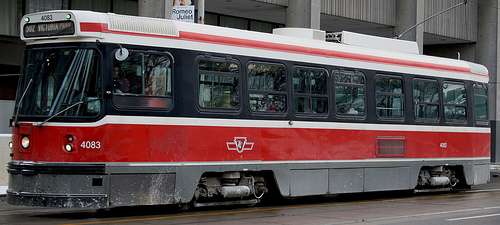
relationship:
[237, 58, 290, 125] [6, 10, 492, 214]
window on bus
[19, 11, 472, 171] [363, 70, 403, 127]
bus has window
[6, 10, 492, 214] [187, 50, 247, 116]
bus has window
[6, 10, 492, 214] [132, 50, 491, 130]
bus has window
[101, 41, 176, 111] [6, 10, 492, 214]
window on bus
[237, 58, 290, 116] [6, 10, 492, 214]
window on bus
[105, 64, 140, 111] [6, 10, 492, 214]
conductor in bus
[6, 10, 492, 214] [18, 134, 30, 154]
bus has headlight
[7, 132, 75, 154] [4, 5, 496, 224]
headlight on train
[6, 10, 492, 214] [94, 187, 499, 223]
bus on street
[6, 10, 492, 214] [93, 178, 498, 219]
bus on road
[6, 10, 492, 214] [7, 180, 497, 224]
bus on road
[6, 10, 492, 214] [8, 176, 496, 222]
bus on road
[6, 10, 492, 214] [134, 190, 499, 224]
bus on street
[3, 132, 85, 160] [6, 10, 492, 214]
headlights on bus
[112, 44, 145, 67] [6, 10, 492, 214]
mirror on bus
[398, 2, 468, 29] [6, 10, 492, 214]
pole connect to bus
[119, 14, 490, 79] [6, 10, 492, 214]
roof on bus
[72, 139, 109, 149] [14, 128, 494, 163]
tram number on background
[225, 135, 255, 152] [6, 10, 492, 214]
design on bus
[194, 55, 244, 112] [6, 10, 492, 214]
window on bus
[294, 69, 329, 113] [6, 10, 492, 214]
window on bus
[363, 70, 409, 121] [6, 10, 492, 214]
window on bus